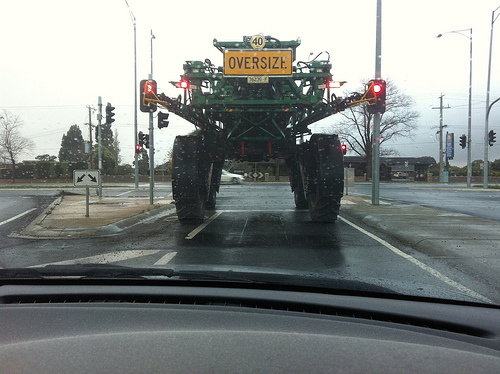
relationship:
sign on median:
[73, 169, 102, 187] [19, 190, 176, 237]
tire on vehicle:
[304, 133, 345, 223] [138, 32, 379, 226]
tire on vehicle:
[304, 133, 345, 223] [138, 32, 391, 231]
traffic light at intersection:
[366, 78, 385, 115] [1, 128, 496, 269]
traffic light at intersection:
[138, 77, 157, 111] [1, 128, 496, 269]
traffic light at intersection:
[487, 129, 494, 146] [1, 128, 496, 269]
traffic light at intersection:
[458, 134, 467, 148] [1, 128, 496, 269]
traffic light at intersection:
[157, 109, 169, 127] [1, 128, 496, 269]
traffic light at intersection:
[105, 102, 116, 127] [1, 128, 496, 269]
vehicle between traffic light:
[138, 32, 379, 226] [367, 79, 386, 115]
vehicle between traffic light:
[138, 32, 379, 226] [140, 79, 157, 113]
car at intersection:
[151, 56, 401, 241] [1, 178, 498, 197]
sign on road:
[443, 131, 462, 168] [14, 171, 498, 324]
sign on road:
[216, 45, 296, 82] [14, 171, 498, 324]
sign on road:
[68, 165, 108, 187] [14, 171, 498, 324]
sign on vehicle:
[224, 50, 293, 76] [138, 32, 379, 226]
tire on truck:
[289, 142, 309, 209] [114, 13, 373, 241]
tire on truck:
[171, 135, 208, 219] [157, 66, 452, 266]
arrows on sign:
[64, 170, 109, 197] [72, 168, 101, 187]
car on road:
[140, 32, 378, 224] [0, 182, 497, 307]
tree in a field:
[1, 109, 34, 166] [36, 119, 117, 156]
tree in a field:
[60, 125, 85, 163] [29, 102, 89, 176]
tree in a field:
[87, 121, 117, 173] [6, 169, 494, 176]